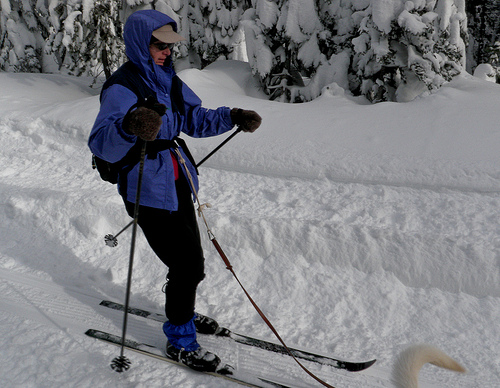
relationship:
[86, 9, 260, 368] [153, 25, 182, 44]
skier has a hat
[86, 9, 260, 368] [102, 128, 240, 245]
skier has a ski pole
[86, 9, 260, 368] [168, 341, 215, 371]
skier has a left boot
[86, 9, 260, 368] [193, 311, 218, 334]
skier has a right boot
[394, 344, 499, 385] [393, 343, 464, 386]
dog has a tail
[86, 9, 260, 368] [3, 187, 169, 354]
skier has a shadow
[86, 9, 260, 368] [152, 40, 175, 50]
skier has on sunglasses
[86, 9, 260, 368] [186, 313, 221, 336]
skier has on a left boot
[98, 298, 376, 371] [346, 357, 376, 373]
ski has a tip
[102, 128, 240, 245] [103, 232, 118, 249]
ski pole has a bottom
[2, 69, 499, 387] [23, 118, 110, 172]
snow has tracks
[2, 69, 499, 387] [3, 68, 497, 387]
snow on ground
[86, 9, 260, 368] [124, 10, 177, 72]
skier has a hood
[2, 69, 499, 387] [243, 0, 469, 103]
snow on a tree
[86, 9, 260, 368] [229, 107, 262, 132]
skier has a glove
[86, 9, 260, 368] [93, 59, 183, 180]
skier has a backpack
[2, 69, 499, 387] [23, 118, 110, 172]
snow on a tracks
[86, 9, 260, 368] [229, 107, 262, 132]
skier wearing a glove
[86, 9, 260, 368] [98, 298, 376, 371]
skier on ski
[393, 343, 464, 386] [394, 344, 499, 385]
tail has a dog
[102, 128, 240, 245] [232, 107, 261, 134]
ski pole in a hand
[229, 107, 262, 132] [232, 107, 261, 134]
glove on a hand